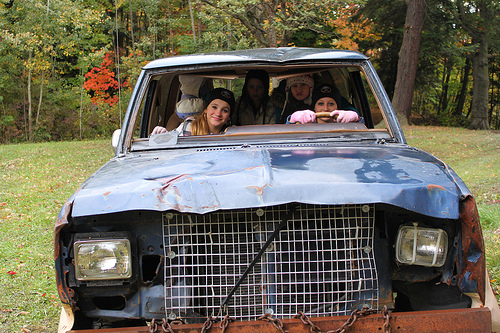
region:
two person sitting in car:
[109, 50, 402, 147]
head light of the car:
[76, 219, 163, 297]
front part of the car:
[174, 228, 412, 325]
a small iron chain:
[150, 310, 420, 329]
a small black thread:
[209, 211, 314, 313]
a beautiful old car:
[61, 31, 481, 317]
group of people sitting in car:
[145, 66, 356, 143]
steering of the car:
[308, 99, 353, 125]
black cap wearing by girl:
[190, 81, 246, 104]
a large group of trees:
[16, 5, 499, 145]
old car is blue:
[110, 46, 457, 300]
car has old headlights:
[70, 220, 452, 275]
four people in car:
[195, 66, 386, 173]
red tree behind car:
[53, 37, 147, 130]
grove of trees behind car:
[35, 6, 147, 123]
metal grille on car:
[151, 140, 391, 312]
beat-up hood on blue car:
[79, 129, 380, 219]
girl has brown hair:
[193, 101, 228, 149]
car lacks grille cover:
[96, 211, 465, 321]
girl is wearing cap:
[172, 81, 245, 140]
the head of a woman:
[200, 83, 240, 129]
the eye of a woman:
[205, 100, 215, 110]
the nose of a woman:
[210, 100, 222, 115]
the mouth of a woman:
[208, 111, 225, 123]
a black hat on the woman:
[200, 83, 240, 114]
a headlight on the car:
[67, 231, 139, 290]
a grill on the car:
[156, 197, 385, 329]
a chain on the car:
[141, 301, 398, 331]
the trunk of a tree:
[387, 0, 430, 120]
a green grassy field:
[0, 124, 499, 331]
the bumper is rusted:
[258, 306, 489, 329]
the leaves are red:
[78, 55, 118, 116]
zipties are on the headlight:
[391, 220, 452, 275]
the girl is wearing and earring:
[198, 107, 209, 123]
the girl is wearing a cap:
[314, 79, 350, 117]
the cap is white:
[280, 77, 319, 83]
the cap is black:
[202, 84, 240, 105]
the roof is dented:
[191, 37, 363, 67]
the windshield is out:
[128, 56, 415, 141]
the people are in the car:
[29, 39, 481, 324]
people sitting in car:
[194, 65, 364, 142]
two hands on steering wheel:
[293, 102, 362, 128]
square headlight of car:
[67, 228, 143, 289]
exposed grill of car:
[203, 217, 365, 311]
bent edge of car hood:
[375, 164, 458, 222]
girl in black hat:
[200, 85, 238, 122]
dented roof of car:
[214, 39, 339, 76]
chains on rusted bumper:
[290, 307, 385, 332]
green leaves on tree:
[13, 9, 79, 59]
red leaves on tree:
[85, 56, 120, 111]